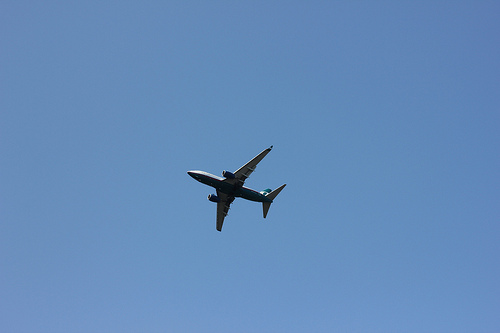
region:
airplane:
[174, 133, 289, 230]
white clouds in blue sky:
[29, 32, 62, 77]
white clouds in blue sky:
[11, 118, 55, 166]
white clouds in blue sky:
[63, 101, 114, 132]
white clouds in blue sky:
[90, 243, 161, 297]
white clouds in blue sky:
[29, 189, 79, 235]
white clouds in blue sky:
[225, 236, 313, 287]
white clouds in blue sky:
[360, 217, 435, 281]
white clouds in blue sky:
[307, 110, 377, 173]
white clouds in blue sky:
[203, 41, 310, 92]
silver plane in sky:
[167, 149, 302, 237]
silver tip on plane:
[187, 158, 218, 189]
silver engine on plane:
[221, 168, 235, 190]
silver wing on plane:
[241, 149, 281, 171]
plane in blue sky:
[193, 158, 348, 253]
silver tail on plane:
[259, 185, 294, 202]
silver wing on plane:
[204, 190, 244, 227]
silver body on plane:
[242, 182, 278, 210]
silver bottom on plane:
[189, 168, 279, 233]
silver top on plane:
[243, 183, 287, 207]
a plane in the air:
[14, 17, 454, 317]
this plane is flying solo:
[152, 145, 309, 242]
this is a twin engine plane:
[199, 162, 238, 212]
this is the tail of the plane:
[253, 185, 294, 238]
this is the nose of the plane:
[180, 161, 200, 183]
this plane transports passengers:
[157, 149, 302, 244]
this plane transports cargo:
[179, 140, 296, 245]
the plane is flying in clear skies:
[77, 76, 443, 294]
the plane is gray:
[137, 138, 312, 233]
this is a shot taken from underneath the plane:
[174, 144, 317, 247]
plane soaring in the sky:
[186, 143, 290, 232]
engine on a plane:
[219, 168, 237, 181]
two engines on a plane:
[205, 168, 237, 204]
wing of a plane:
[226, 140, 275, 187]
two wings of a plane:
[212, 142, 272, 236]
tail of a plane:
[259, 181, 286, 219]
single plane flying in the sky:
[184, 143, 294, 234]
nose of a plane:
[184, 167, 208, 180]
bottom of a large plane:
[184, 144, 293, 232]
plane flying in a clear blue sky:
[1, 0, 498, 330]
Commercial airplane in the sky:
[177, 143, 297, 240]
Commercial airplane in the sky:
[173, 164, 229, 211]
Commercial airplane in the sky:
[227, 168, 295, 230]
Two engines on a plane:
[196, 153, 252, 212]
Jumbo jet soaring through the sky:
[173, 151, 307, 237]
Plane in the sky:
[176, 133, 308, 243]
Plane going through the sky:
[163, 128, 300, 240]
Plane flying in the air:
[175, 125, 311, 245]